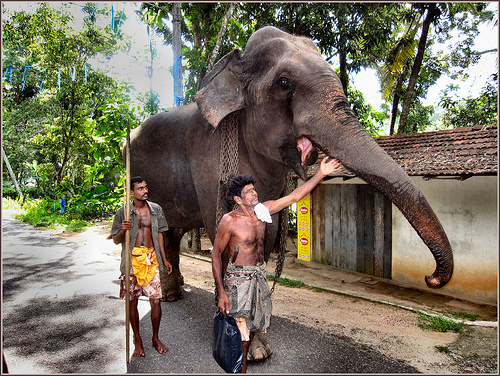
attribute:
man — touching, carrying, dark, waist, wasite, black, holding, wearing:
[193, 155, 315, 375]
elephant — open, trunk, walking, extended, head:
[112, 1, 379, 261]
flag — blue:
[55, 184, 73, 218]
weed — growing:
[8, 166, 124, 253]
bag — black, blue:
[192, 302, 243, 372]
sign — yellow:
[304, 206, 315, 240]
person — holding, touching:
[86, 157, 186, 343]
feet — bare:
[124, 323, 175, 368]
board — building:
[320, 192, 383, 301]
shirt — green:
[150, 191, 175, 242]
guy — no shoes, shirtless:
[105, 255, 165, 349]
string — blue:
[206, 296, 245, 350]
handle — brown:
[111, 153, 144, 200]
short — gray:
[225, 269, 285, 314]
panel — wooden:
[335, 184, 384, 265]